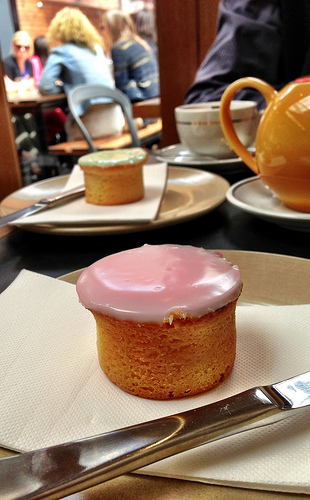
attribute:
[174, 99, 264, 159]
cup — white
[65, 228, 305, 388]
plate — round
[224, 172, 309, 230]
saucer — white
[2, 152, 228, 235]
plate — brown, frosted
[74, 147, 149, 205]
cupcake — yellow, frosted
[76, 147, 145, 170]
frosting — green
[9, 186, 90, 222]
butterknife — silver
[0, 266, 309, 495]
napkin — white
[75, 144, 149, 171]
frosting — yellow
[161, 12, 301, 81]
person — sitting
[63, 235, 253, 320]
icing — pink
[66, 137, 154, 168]
icing — green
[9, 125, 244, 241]
plate — round, white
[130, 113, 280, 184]
saucer — white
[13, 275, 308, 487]
napkin — white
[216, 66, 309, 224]
kettle — orange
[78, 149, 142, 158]
icing — green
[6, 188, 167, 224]
napkin — white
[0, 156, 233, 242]
plate — light, brown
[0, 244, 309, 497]
plate — light, brown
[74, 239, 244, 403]
cupcake — frosted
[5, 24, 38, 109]
woman — group, sitting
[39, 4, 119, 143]
woman — group, sitting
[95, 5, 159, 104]
woman — group, sitting